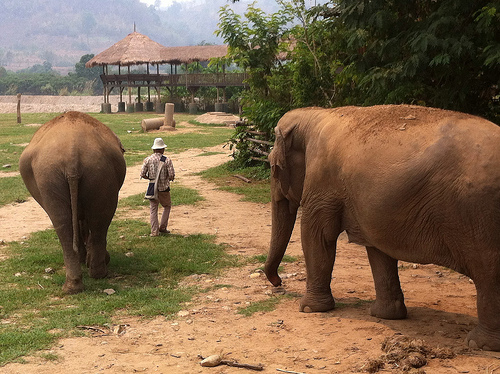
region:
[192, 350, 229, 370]
a grey rock on ground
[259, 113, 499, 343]
a large elephant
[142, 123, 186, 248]
a man in white hat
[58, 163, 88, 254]
a elephant tail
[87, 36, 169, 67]
a tan roof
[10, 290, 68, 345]
green grass growing on ground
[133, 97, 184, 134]
two large wooden logs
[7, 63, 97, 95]
bushes with green leaves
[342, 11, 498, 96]
a tree with large green leaves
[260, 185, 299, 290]
a elephant trunk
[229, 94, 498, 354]
an elephant covered in dirt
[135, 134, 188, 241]
a man with a satchel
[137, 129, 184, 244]
a man wearing a brown hat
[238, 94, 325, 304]
the head, ears, and trunk of an elephant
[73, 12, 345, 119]
a wooden structure with a leaf thatched roof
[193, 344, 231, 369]
a rock on the ground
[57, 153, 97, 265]
an elephant's tail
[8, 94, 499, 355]
two elephants and a man walking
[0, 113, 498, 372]
dirt trails leading to a wooden structure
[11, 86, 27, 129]
a wooden post in the ground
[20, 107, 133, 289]
the back side of an elephant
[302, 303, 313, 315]
an elephant toenail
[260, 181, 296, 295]
a long elephant trunk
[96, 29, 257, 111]
a covered walkway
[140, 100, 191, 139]
two poured concrete pillars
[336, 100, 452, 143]
dirt on an elephant back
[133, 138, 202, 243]
a man walking by an elephant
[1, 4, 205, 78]
a mountain in the background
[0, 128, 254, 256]
a brown dirt path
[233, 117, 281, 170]
a wood rail fence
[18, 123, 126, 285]
Back of a large brown elephant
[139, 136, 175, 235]
man walking next to an elephant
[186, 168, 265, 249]
a dirt pathway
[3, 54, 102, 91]
a row of trees and bushes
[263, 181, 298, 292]
trunk of an elephant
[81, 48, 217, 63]
a thatched roof over a deck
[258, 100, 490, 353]
a large brown elephant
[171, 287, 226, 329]
rocks scattered in the dirt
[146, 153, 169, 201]
a gray and blue shoulder bag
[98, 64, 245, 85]
a wooden deck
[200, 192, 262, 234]
the sand is brown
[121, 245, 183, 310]
the grass is green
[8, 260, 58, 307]
the rocks in grass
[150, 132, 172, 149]
the hat is white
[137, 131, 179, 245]
the bag is on person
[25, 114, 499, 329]
the elephants are brown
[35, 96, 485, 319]
two elephants are seen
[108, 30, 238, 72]
the hut roofs are made of straw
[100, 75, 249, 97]
bridge is made of wood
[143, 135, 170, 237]
one person is seen